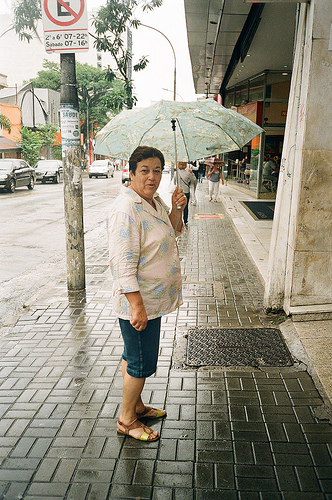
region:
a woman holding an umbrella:
[105, 77, 203, 452]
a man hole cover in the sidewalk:
[184, 319, 289, 375]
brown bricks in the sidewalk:
[24, 343, 62, 367]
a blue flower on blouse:
[119, 228, 134, 238]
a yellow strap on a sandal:
[138, 432, 150, 441]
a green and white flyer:
[56, 100, 83, 146]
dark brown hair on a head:
[133, 146, 155, 159]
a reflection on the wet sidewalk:
[63, 312, 100, 376]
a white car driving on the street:
[84, 158, 117, 178]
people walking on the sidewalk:
[179, 161, 234, 221]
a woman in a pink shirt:
[109, 142, 184, 444]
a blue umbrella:
[92, 98, 265, 208]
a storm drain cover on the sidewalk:
[184, 327, 294, 368]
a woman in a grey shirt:
[170, 160, 198, 225]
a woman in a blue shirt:
[206, 159, 224, 201]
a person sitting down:
[262, 156, 276, 190]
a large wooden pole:
[55, 48, 91, 291]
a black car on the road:
[0, 158, 35, 188]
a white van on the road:
[88, 158, 112, 177]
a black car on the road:
[32, 157, 63, 184]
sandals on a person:
[110, 404, 165, 445]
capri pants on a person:
[115, 287, 161, 382]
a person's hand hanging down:
[126, 306, 149, 332]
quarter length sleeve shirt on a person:
[106, 183, 187, 324]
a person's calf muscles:
[115, 358, 144, 415]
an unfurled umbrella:
[90, 95, 263, 164]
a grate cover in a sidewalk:
[182, 323, 296, 370]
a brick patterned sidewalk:
[169, 372, 297, 442]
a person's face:
[126, 144, 162, 194]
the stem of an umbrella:
[165, 115, 188, 207]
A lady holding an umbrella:
[91, 95, 265, 445]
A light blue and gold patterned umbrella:
[92, 98, 266, 210]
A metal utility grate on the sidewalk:
[185, 323, 296, 374]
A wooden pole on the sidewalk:
[35, 53, 101, 292]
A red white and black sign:
[39, 0, 94, 54]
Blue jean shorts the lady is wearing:
[117, 314, 162, 380]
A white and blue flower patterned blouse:
[104, 183, 185, 318]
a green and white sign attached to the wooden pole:
[58, 104, 80, 146]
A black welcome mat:
[237, 198, 274, 223]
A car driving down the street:
[88, 159, 115, 179]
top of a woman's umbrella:
[92, 97, 265, 166]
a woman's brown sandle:
[116, 415, 161, 441]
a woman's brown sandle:
[132, 403, 166, 419]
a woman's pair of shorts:
[117, 317, 162, 377]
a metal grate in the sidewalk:
[186, 327, 291, 369]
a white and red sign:
[41, 0, 89, 54]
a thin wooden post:
[57, 51, 85, 290]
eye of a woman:
[140, 168, 149, 173]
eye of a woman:
[153, 168, 159, 173]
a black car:
[0, 158, 36, 192]